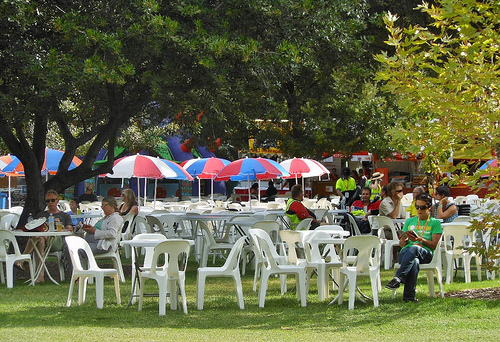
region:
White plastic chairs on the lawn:
[0, 196, 485, 303]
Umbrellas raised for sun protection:
[0, 141, 343, 207]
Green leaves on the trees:
[0, 25, 491, 186]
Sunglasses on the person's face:
[410, 200, 432, 215]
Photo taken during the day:
[6, 8, 492, 333]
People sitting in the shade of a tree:
[2, 191, 137, 271]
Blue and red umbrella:
[212, 155, 292, 182]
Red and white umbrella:
[282, 155, 321, 185]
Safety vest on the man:
[282, 191, 308, 236]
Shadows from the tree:
[9, 286, 463, 332]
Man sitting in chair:
[381, 190, 438, 306]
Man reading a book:
[386, 190, 444, 301]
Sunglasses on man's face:
[410, 201, 432, 211]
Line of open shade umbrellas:
[3, 150, 325, 201]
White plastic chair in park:
[57, 233, 123, 313]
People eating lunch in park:
[10, 193, 123, 283]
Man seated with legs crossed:
[385, 192, 445, 308]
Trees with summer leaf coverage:
[6, 6, 488, 167]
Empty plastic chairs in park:
[52, 232, 390, 313]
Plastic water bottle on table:
[46, 210, 56, 235]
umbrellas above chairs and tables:
[111, 142, 333, 195]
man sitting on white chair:
[360, 182, 448, 317]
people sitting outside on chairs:
[28, 182, 150, 268]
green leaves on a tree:
[391, 28, 481, 155]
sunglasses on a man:
[413, 198, 433, 213]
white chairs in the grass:
[52, 231, 223, 313]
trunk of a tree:
[8, 123, 80, 199]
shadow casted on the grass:
[196, 307, 370, 334]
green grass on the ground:
[394, 314, 497, 336]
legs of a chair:
[61, 275, 131, 308]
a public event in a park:
[18, 58, 496, 295]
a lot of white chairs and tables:
[4, 137, 460, 281]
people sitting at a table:
[19, 164, 166, 286]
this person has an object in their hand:
[365, 173, 457, 318]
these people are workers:
[283, 155, 393, 222]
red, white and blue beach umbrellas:
[88, 124, 319, 191]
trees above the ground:
[42, 24, 454, 156]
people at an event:
[346, 112, 487, 224]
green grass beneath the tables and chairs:
[45, 283, 440, 324]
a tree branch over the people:
[9, 102, 135, 207]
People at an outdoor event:
[0, 136, 498, 324]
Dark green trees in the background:
[0, 1, 417, 222]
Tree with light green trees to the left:
[360, 1, 499, 198]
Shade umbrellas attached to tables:
[0, 136, 335, 205]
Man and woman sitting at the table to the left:
[28, 188, 126, 288]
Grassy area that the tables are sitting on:
[0, 253, 499, 340]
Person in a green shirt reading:
[381, 193, 441, 308]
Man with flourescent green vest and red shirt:
[276, 181, 318, 225]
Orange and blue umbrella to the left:
[3, 144, 87, 179]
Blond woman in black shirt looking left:
[110, 183, 145, 219]